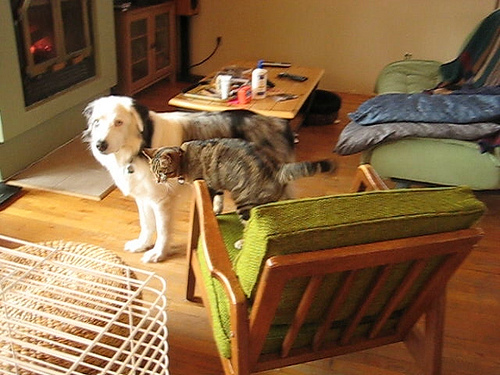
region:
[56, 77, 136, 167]
face of the dog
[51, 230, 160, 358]
a small iron stand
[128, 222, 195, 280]
leg of the dog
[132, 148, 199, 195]
face of the cat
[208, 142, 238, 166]
skin of the cat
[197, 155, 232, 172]
fur of the cat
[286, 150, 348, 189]
tail of the cat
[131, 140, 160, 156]
a tag to dog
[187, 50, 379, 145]
a table beside the dog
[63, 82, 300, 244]
a dog and a cat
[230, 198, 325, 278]
the chair cushion is green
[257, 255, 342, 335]
the chair is made of wood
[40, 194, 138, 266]
the floor is made of wood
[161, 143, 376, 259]
the cat is black and gray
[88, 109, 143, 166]
the dog has a white face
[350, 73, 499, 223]
the cushions are on the couch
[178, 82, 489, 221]
the table is made of wood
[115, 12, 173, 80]
a wooden cabinet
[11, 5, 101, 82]
a fireplace in the wall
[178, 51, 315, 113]
a coffee table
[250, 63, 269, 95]
a white bottle on the coffee table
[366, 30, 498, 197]
a green couch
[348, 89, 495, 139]
pillows on the couch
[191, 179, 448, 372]
a green chair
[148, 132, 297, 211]
a cat standing on the chair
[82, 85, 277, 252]
a black and white dog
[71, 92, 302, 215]
a dog and a cat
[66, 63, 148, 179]
face of the dog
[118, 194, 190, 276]
leg of the dog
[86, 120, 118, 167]
mouth of the dog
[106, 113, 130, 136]
eye of the dog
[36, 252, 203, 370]
a iron stand near chair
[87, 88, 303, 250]
a dog in the floor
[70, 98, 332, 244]
a dog in the wood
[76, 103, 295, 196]
cat and dog in the room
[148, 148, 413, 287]
cat on the green chair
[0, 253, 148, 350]
basket weave hassock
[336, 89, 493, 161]
two pillows on the sofa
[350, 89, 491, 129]
top pillow is blue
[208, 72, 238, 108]
white cup on the table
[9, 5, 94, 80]
fireplace in the wall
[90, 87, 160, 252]
dog is white and black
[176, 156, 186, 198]
bell is on neck of cat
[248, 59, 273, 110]
bottle on the table